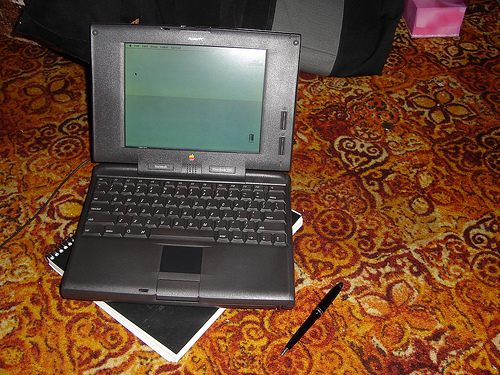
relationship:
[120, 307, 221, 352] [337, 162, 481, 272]
notebook on carpet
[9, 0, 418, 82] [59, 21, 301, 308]
bag behind laptop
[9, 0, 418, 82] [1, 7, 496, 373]
bag on carpet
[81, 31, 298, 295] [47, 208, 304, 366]
laptop on notebook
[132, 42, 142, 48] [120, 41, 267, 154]
tab on screen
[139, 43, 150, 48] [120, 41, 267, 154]
tab on screen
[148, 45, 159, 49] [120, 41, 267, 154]
tab on screen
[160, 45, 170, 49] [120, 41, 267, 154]
tab on screen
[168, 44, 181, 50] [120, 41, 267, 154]
tab on screen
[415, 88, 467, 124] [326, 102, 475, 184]
design on carpet